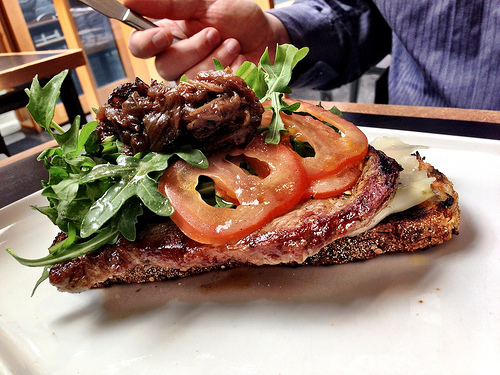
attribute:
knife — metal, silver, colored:
[81, 0, 173, 39]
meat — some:
[67, 219, 467, 294]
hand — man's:
[119, 0, 297, 94]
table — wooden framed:
[0, 48, 92, 163]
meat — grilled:
[36, 160, 461, 293]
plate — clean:
[5, 251, 493, 368]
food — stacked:
[14, 42, 461, 299]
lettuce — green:
[37, 115, 150, 237]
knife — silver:
[87, 2, 198, 48]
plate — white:
[115, 269, 479, 360]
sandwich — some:
[55, 72, 442, 278]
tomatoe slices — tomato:
[153, 86, 375, 253]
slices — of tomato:
[158, 114, 371, 231]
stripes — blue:
[376, 3, 496, 115]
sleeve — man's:
[264, 0, 392, 93]